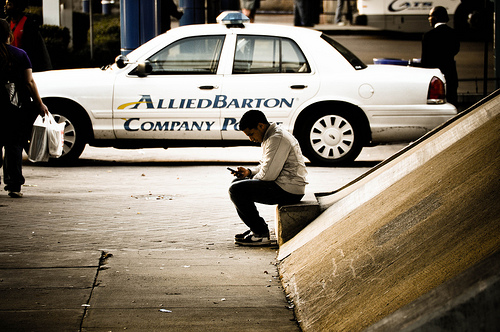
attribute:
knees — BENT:
[223, 175, 269, 201]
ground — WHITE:
[132, 166, 217, 250]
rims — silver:
[308, 112, 354, 159]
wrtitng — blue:
[128, 85, 213, 115]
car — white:
[20, 8, 467, 163]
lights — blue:
[192, 0, 256, 27]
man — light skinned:
[226, 105, 312, 257]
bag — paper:
[44, 115, 68, 160]